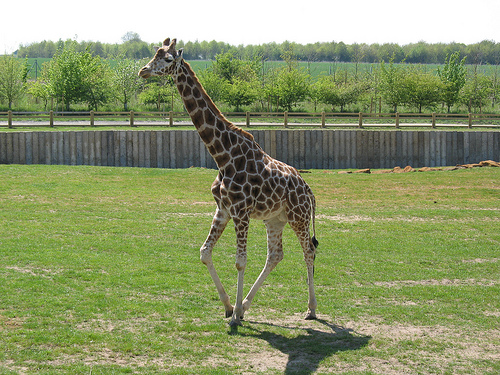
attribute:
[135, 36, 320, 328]
giraffe — tall, standing, white, walking, present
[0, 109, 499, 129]
fence — wooden, wood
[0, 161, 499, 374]
grass — green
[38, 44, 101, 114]
tree — green, present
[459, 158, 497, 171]
rocks — brown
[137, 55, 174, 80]
face — white